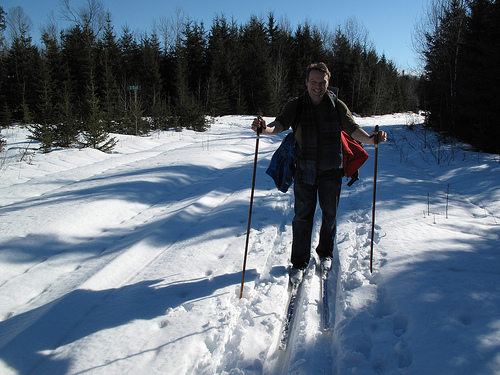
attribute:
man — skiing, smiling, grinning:
[252, 61, 389, 278]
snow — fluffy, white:
[1, 111, 499, 375]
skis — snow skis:
[277, 275, 339, 350]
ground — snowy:
[1, 107, 499, 373]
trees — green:
[2, 0, 499, 158]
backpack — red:
[339, 129, 367, 179]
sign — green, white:
[126, 85, 144, 92]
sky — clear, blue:
[3, 1, 500, 77]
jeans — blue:
[289, 164, 343, 271]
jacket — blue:
[275, 89, 360, 172]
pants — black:
[287, 167, 342, 267]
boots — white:
[289, 253, 332, 285]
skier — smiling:
[252, 61, 390, 284]